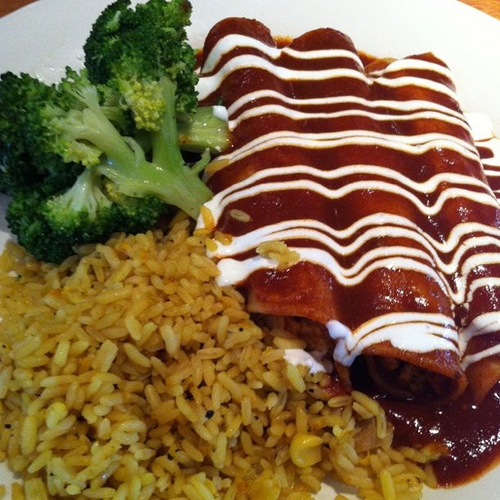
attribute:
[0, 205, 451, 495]
rice — yellowish, cooked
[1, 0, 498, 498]
plate — White, round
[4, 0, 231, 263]
broccoli — green, cooked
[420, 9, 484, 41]
plate — white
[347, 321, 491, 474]
sauce — red